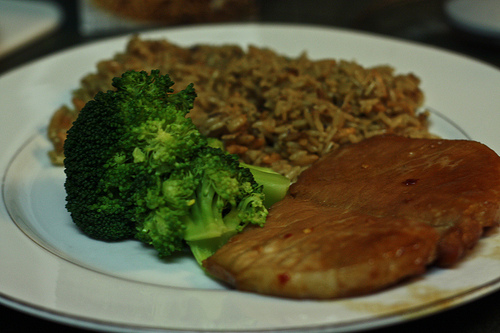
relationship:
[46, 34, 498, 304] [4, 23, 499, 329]
food on plate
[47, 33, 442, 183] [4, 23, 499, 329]
rice on plate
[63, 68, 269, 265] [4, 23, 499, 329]
broccoli on plate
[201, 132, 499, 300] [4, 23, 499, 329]
pork chop on plate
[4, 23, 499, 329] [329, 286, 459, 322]
plate has stain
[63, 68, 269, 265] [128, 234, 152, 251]
broccoli has shadow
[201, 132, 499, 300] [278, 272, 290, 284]
pork chop has mark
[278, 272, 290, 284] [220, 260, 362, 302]
mark on edge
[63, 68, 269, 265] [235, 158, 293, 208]
broccoli has stalk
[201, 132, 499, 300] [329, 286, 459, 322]
pork chop makes stain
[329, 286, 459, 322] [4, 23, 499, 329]
stain on plate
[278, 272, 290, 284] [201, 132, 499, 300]
mark on pork chop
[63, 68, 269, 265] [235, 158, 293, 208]
broccoli has stem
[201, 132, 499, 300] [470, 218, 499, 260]
pork chop has sauce